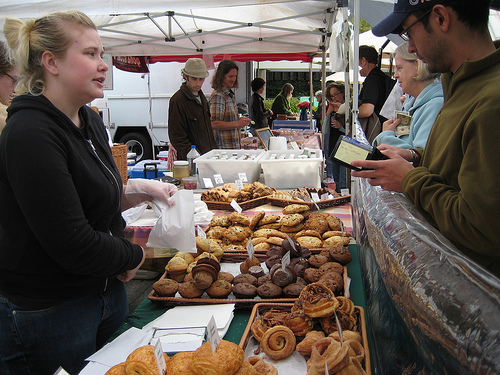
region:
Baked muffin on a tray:
[152, 277, 179, 298]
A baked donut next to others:
[259, 326, 295, 359]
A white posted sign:
[205, 315, 221, 352]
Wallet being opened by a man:
[330, 133, 400, 177]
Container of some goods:
[190, 148, 262, 192]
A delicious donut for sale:
[297, 283, 337, 316]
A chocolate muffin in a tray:
[231, 280, 256, 296]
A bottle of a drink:
[186, 143, 200, 177]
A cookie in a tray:
[296, 233, 321, 249]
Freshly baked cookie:
[227, 211, 249, 224]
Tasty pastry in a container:
[258, 325, 295, 361]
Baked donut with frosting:
[297, 282, 336, 317]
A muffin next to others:
[151, 278, 178, 298]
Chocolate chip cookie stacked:
[280, 213, 302, 225]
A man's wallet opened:
[329, 134, 392, 179]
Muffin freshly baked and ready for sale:
[163, 256, 188, 281]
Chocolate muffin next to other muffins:
[232, 280, 256, 299]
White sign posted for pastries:
[205, 316, 220, 352]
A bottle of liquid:
[185, 144, 200, 174]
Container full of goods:
[191, 147, 262, 184]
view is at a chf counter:
[113, 103, 485, 327]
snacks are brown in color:
[228, 202, 349, 284]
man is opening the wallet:
[344, 34, 499, 179]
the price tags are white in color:
[198, 301, 235, 356]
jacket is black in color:
[13, 102, 116, 294]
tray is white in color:
[266, 145, 334, 190]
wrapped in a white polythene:
[153, 209, 205, 239]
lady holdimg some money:
[381, 58, 440, 143]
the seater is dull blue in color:
[390, 102, 447, 157]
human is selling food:
[0, 10, 147, 374]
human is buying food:
[330, 0, 499, 275]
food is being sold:
[104, 172, 369, 374]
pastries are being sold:
[110, 182, 369, 374]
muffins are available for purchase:
[153, 249, 349, 297]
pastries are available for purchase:
[242, 282, 368, 374]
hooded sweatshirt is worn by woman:
[1, 90, 141, 298]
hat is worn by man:
[180, 58, 209, 79]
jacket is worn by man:
[165, 81, 212, 154]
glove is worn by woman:
[120, 176, 181, 211]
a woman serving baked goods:
[0, 12, 149, 373]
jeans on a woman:
[2, 274, 132, 374]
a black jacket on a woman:
[0, 87, 146, 309]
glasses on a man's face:
[396, 12, 434, 44]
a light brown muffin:
[165, 255, 187, 284]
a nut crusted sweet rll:
[297, 280, 337, 318]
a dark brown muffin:
[282, 235, 306, 260]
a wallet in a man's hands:
[325, 129, 394, 183]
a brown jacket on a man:
[162, 81, 217, 162]